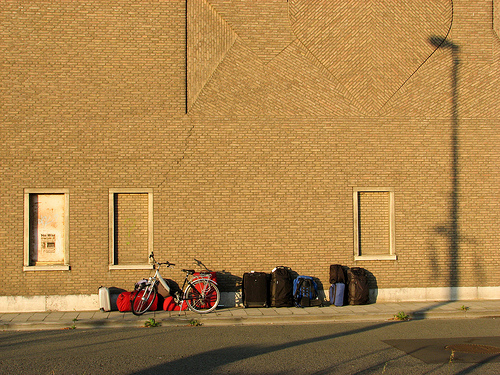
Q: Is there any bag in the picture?
A: Yes, there is a bag.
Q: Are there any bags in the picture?
A: Yes, there is a bag.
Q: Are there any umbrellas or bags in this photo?
A: Yes, there is a bag.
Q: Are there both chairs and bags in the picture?
A: No, there is a bag but no chairs.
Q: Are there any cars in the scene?
A: No, there are no cars.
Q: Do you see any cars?
A: No, there are no cars.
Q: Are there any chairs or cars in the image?
A: No, there are no cars or chairs.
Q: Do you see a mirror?
A: No, there are no mirrors.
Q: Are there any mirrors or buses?
A: No, there are no mirrors or buses.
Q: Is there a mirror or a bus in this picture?
A: No, there are no mirrors or buses.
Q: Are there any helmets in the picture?
A: No, there are no helmets.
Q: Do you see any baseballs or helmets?
A: No, there are no helmets or baseballs.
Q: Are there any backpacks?
A: Yes, there is a backpack.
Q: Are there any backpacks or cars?
A: Yes, there is a backpack.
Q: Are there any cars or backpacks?
A: Yes, there is a backpack.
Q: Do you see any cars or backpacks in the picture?
A: Yes, there is a backpack.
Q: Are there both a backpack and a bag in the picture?
A: Yes, there are both a backpack and a bag.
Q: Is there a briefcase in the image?
A: No, there are no briefcases.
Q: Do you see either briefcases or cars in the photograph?
A: No, there are no briefcases or cars.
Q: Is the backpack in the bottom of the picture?
A: Yes, the backpack is in the bottom of the image.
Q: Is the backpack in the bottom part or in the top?
A: The backpack is in the bottom of the image.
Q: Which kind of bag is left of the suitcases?
A: The bag is a backpack.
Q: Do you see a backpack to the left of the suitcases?
A: Yes, there is a backpack to the left of the suitcases.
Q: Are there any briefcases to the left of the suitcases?
A: No, there is a backpack to the left of the suitcases.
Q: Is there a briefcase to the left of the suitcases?
A: No, there is a backpack to the left of the suitcases.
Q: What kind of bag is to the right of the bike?
A: The bag is a backpack.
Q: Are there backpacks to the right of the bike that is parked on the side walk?
A: Yes, there is a backpack to the right of the bike.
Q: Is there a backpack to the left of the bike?
A: No, the backpack is to the right of the bike.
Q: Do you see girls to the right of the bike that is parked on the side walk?
A: No, there is a backpack to the right of the bike.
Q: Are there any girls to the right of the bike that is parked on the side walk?
A: No, there is a backpack to the right of the bike.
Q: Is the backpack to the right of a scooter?
A: No, the backpack is to the right of the bike.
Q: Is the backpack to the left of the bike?
A: No, the backpack is to the right of the bike.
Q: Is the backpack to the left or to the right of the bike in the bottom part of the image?
A: The backpack is to the right of the bike.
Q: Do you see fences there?
A: No, there are no fences.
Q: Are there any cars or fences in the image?
A: No, there are no fences or cars.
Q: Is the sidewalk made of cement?
A: Yes, the sidewalk is made of cement.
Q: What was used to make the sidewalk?
A: The sidewalk is made of cement.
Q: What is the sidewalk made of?
A: The sidewalk is made of concrete.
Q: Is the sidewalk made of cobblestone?
A: No, the sidewalk is made of cement.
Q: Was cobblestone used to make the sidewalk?
A: No, the sidewalk is made of cement.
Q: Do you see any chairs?
A: No, there are no chairs.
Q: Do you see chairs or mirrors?
A: No, there are no chairs or mirrors.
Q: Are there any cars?
A: No, there are no cars.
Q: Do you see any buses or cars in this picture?
A: No, there are no cars or buses.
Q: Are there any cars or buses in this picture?
A: No, there are no cars or buses.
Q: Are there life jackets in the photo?
A: No, there are no life jackets.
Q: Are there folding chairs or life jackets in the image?
A: No, there are no life jackets or folding chairs.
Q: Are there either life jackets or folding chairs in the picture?
A: No, there are no life jackets or folding chairs.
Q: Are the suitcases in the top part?
A: No, the suitcases are in the bottom of the image.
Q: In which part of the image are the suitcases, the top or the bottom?
A: The suitcases are in the bottom of the image.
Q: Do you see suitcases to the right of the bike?
A: Yes, there are suitcases to the right of the bike.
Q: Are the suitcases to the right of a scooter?
A: No, the suitcases are to the right of a bike.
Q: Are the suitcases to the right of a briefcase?
A: No, the suitcases are to the right of a backpack.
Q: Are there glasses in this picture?
A: No, there are no glasses.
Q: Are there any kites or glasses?
A: No, there are no glasses or kites.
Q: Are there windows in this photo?
A: Yes, there is a window.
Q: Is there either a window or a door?
A: Yes, there is a window.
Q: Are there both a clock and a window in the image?
A: No, there is a window but no clocks.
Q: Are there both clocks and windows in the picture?
A: No, there is a window but no clocks.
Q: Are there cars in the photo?
A: No, there are no cars.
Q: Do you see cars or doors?
A: No, there are no cars or doors.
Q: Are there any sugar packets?
A: No, there are no sugar packets.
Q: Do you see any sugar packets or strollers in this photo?
A: No, there are no sugar packets or strollers.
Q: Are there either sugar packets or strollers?
A: No, there are no sugar packets or strollers.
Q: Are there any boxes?
A: No, there are no boxes.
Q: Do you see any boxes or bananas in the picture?
A: No, there are no boxes or bananas.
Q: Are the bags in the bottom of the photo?
A: Yes, the bags are in the bottom of the image.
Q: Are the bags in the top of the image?
A: No, the bags are in the bottom of the image.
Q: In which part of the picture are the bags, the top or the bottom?
A: The bags are in the bottom of the image.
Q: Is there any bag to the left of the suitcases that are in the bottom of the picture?
A: Yes, there are bags to the left of the suitcases.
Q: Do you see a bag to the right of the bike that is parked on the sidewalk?
A: Yes, there are bags to the right of the bike.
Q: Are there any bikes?
A: Yes, there is a bike.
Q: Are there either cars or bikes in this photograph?
A: Yes, there is a bike.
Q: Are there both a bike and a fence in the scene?
A: No, there is a bike but no fences.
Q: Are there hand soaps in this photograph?
A: No, there are no hand soaps.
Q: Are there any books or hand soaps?
A: No, there are no hand soaps or books.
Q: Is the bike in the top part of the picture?
A: No, the bike is in the bottom of the image.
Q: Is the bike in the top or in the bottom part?
A: The bike is in the bottom of the image.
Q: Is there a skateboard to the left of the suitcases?
A: No, there is a bike to the left of the suitcases.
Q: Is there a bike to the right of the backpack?
A: No, the bike is to the left of the backpack.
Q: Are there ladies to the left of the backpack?
A: No, there is a bike to the left of the backpack.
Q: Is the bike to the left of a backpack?
A: Yes, the bike is to the left of a backpack.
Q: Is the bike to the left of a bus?
A: No, the bike is to the left of a backpack.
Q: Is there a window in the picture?
A: Yes, there are windows.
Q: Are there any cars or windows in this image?
A: Yes, there are windows.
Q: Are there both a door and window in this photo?
A: No, there are windows but no doors.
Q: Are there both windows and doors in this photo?
A: No, there are windows but no doors.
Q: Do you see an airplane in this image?
A: No, there are no airplanes.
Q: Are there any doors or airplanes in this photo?
A: No, there are no airplanes or doors.